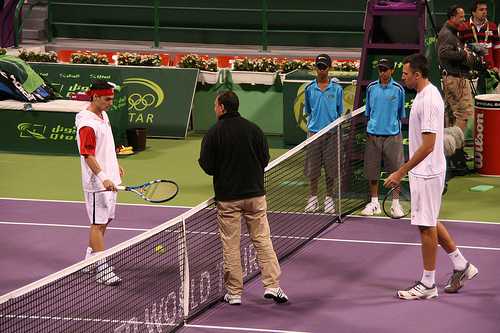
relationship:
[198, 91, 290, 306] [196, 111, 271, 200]
man wearing jacket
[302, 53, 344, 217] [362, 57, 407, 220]
man matches man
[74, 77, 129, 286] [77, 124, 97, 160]
man has sleeve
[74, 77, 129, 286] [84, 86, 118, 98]
man has headband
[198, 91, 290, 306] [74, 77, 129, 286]
man talking to man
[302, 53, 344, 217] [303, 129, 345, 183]
man wearing shorts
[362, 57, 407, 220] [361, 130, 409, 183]
man wearing shorts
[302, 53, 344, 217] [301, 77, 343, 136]
man wearing shirt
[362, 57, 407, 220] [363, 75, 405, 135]
man wearing shirt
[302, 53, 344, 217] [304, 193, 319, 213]
man wearing shoe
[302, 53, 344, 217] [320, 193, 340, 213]
man wearing shoe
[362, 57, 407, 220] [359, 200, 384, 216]
man wearing shoe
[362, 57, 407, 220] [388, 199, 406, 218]
man wearing shoe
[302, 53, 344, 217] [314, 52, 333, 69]
man wearing cap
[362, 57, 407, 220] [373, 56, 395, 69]
man wearing cap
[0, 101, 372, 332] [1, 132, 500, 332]
net stretched across tennis court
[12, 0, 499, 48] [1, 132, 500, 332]
railing around tennis court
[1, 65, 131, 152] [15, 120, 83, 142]
table has logo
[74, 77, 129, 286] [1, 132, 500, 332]
man on tennis court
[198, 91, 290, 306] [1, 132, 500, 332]
man on tennis court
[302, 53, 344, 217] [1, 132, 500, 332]
man on tennis court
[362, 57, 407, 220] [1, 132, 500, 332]
man on tennis court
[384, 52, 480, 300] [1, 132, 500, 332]
player on tennis court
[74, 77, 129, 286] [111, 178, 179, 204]
man holding tennis racket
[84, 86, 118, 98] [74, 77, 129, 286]
headband on man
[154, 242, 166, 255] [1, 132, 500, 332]
ball on tennis court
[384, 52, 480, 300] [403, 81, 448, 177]
player wearing shirt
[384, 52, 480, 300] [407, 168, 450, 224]
player wearing shorts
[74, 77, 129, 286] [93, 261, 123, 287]
man wearing shoe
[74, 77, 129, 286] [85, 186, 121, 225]
man wearing shorts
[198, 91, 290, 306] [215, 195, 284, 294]
man wearing pants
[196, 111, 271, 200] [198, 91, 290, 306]
jacket on man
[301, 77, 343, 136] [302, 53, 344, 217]
shirt on man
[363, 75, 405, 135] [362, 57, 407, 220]
shirt on man